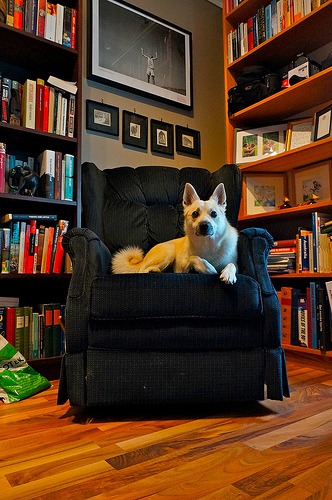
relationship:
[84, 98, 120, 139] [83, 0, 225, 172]
frame on wall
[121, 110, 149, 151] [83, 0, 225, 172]
frame on wall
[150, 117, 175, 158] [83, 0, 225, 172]
frame on wall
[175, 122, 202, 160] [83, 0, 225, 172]
frame on wall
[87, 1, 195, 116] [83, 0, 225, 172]
frame on wall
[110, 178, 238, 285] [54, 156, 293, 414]
dog in chair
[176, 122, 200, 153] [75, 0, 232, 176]
picture on wall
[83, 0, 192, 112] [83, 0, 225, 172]
picture on wall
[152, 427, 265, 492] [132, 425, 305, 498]
floor has part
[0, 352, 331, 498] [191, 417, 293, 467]
floor has part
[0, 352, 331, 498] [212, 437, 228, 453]
floor has part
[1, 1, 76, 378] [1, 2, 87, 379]
books on book shelf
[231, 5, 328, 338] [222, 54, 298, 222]
books in shelf